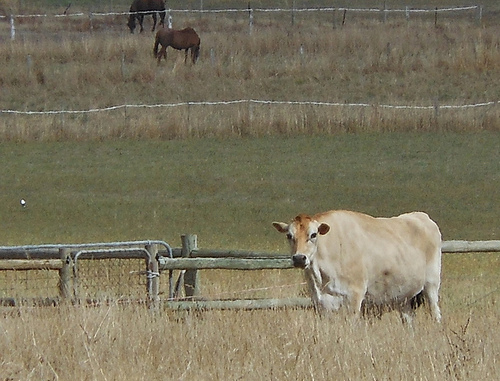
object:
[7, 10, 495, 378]
pasture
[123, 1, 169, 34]
horse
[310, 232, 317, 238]
eye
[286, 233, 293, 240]
eye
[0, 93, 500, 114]
rope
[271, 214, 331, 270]
head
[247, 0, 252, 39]
pole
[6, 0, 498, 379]
field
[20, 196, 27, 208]
bird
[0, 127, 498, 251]
grass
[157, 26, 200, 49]
black shirt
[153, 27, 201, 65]
brown horse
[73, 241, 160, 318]
gate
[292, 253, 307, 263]
nose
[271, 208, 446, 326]
cow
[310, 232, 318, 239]
black eye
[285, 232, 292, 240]
black eye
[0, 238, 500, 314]
fence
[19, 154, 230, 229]
green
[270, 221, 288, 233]
ear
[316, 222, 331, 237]
ear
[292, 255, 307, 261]
nostril